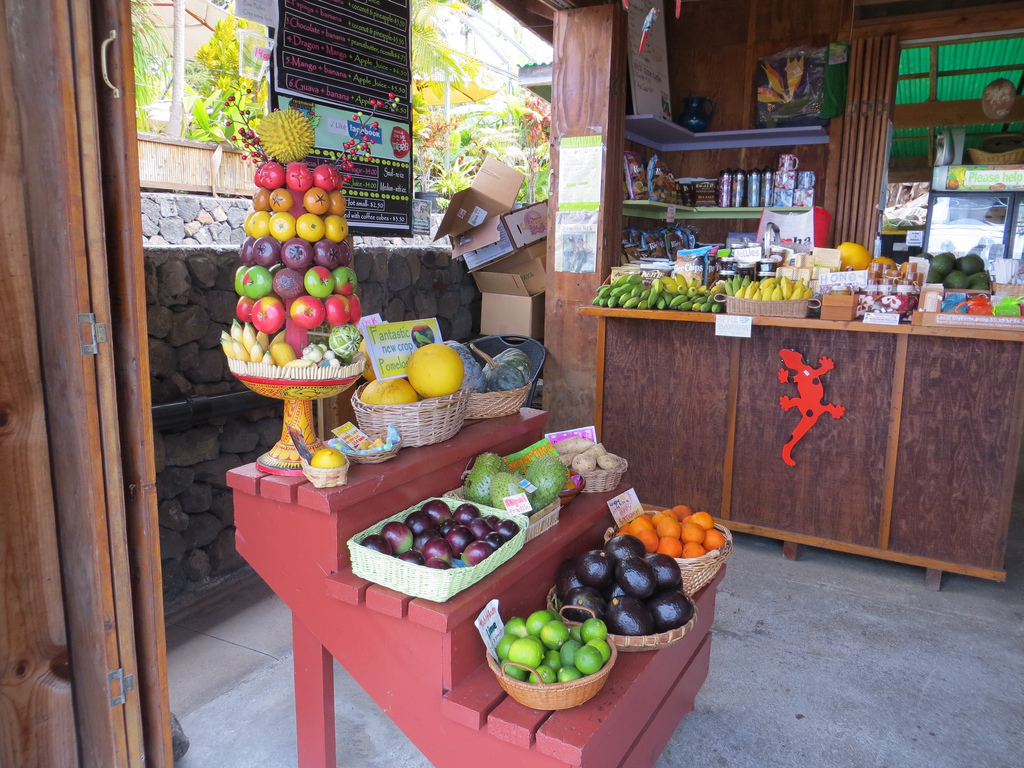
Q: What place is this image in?
A: It is at the display.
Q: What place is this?
A: It is a display.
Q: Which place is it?
A: It is a display.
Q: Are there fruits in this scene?
A: Yes, there is a fruit.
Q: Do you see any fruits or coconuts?
A: Yes, there is a fruit.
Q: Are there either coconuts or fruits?
A: Yes, there is a fruit.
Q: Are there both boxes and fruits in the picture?
A: Yes, there are both a fruit and a box.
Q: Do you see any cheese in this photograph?
A: No, there is no cheese.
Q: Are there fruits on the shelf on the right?
A: Yes, there is a fruit on the shelf.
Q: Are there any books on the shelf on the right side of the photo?
A: No, there is a fruit on the shelf.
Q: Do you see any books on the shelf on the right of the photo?
A: No, there is a fruit on the shelf.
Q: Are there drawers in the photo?
A: No, there are no drawers.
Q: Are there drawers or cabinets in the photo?
A: No, there are no drawers or cabinets.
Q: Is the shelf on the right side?
A: Yes, the shelf is on the right of the image.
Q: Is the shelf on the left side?
A: No, the shelf is on the right of the image.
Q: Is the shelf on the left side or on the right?
A: The shelf is on the right of the image.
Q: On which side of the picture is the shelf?
A: The shelf is on the right of the image.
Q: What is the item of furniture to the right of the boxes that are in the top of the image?
A: The piece of furniture is a shelf.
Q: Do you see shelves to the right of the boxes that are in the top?
A: Yes, there is a shelf to the right of the boxes.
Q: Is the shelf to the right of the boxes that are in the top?
A: Yes, the shelf is to the right of the boxes.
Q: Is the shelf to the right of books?
A: No, the shelf is to the right of the boxes.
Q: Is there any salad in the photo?
A: No, there is no salad.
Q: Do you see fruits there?
A: Yes, there is a fruit.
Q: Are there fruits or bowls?
A: Yes, there is a fruit.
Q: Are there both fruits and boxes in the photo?
A: Yes, there are both a fruit and a box.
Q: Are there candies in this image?
A: No, there are no candies.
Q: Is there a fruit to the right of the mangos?
A: Yes, there is a fruit to the right of the mangos.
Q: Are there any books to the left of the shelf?
A: No, there are boxes to the left of the shelf.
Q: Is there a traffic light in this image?
A: No, there are no traffic lights.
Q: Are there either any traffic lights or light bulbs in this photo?
A: No, there are no traffic lights or light bulbs.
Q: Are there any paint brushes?
A: No, there are no paint brushes.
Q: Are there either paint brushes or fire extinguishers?
A: No, there are no paint brushes or fire extinguishers.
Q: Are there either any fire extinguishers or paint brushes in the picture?
A: No, there are no paint brushes or fire extinguishers.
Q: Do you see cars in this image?
A: No, there are no cars.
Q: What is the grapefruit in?
A: The grapefruit is in the basket.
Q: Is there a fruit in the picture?
A: Yes, there is a fruit.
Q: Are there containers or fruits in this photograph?
A: Yes, there is a fruit.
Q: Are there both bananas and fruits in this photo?
A: Yes, there are both a fruit and a banana.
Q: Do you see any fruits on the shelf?
A: Yes, there is a fruit on the shelf.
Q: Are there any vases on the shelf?
A: No, there is a fruit on the shelf.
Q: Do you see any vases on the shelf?
A: No, there is a fruit on the shelf.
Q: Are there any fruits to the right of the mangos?
A: Yes, there is a fruit to the right of the mangos.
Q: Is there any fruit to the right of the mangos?
A: Yes, there is a fruit to the right of the mangos.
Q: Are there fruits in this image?
A: Yes, there is a fruit.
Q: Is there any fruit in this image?
A: Yes, there is a fruit.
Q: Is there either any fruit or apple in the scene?
A: Yes, there is a fruit.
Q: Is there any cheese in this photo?
A: No, there is no cheese.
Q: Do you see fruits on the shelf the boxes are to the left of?
A: Yes, there is a fruit on the shelf.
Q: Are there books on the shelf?
A: No, there is a fruit on the shelf.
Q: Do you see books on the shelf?
A: No, there is a fruit on the shelf.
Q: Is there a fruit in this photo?
A: Yes, there is a fruit.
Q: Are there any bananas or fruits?
A: Yes, there is a fruit.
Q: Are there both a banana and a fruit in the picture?
A: Yes, there are both a fruit and a banana.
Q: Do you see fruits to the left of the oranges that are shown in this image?
A: Yes, there is a fruit to the left of the oranges.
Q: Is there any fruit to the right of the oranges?
A: No, the fruit is to the left of the oranges.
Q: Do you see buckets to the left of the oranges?
A: No, there is a fruit to the left of the oranges.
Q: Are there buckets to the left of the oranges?
A: No, there is a fruit to the left of the oranges.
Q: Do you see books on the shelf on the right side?
A: No, there is a fruit on the shelf.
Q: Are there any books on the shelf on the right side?
A: No, there is a fruit on the shelf.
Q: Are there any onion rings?
A: No, there are no onion rings.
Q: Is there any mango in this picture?
A: Yes, there are mangoes.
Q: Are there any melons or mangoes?
A: Yes, there are mangoes.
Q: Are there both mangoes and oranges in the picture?
A: Yes, there are both mangoes and oranges.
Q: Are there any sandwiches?
A: No, there are no sandwiches.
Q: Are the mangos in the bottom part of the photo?
A: Yes, the mangos are in the bottom of the image.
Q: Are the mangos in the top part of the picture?
A: No, the mangos are in the bottom of the image.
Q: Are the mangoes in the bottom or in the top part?
A: The mangoes are in the bottom of the image.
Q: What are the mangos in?
A: The mangos are in the basket.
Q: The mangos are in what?
A: The mangos are in the basket.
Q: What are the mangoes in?
A: The mangos are in the basket.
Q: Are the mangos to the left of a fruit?
A: Yes, the mangos are to the left of a fruit.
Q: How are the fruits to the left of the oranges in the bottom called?
A: The fruits are mangoes.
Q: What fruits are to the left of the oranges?
A: The fruits are mangoes.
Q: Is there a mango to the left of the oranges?
A: Yes, there are mangoes to the left of the oranges.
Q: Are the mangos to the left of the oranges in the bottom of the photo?
A: Yes, the mangos are to the left of the oranges.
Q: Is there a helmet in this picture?
A: No, there are no helmets.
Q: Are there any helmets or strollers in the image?
A: No, there are no helmets or strollers.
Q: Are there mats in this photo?
A: No, there are no mats.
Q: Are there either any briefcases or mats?
A: No, there are no mats or briefcases.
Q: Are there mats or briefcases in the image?
A: No, there are no mats or briefcases.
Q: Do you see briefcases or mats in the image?
A: No, there are no mats or briefcases.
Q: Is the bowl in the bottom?
A: Yes, the bowl is in the bottom of the image.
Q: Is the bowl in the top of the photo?
A: No, the bowl is in the bottom of the image.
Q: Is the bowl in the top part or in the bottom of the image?
A: The bowl is in the bottom of the image.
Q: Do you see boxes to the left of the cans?
A: Yes, there are boxes to the left of the cans.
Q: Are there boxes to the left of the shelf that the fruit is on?
A: Yes, there are boxes to the left of the shelf.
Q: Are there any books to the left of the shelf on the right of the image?
A: No, there are boxes to the left of the shelf.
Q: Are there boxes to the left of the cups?
A: Yes, there are boxes to the left of the cups.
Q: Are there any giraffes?
A: No, there are no giraffes.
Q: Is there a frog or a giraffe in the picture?
A: No, there are no giraffes or frogs.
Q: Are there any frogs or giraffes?
A: No, there are no giraffes or frogs.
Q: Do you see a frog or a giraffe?
A: No, there are no giraffes or frogs.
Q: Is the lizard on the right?
A: Yes, the lizard is on the right of the image.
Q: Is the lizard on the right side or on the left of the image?
A: The lizard is on the right of the image.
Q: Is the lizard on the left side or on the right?
A: The lizard is on the right of the image.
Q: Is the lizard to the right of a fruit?
A: Yes, the lizard is to the right of a fruit.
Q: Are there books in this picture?
A: No, there are no books.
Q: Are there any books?
A: No, there are no books.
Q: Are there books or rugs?
A: No, there are no books or rugs.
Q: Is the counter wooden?
A: Yes, the counter is wooden.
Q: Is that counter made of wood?
A: Yes, the counter is made of wood.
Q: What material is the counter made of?
A: The counter is made of wood.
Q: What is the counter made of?
A: The counter is made of wood.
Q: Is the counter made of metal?
A: No, the counter is made of wood.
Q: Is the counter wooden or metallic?
A: The counter is wooden.